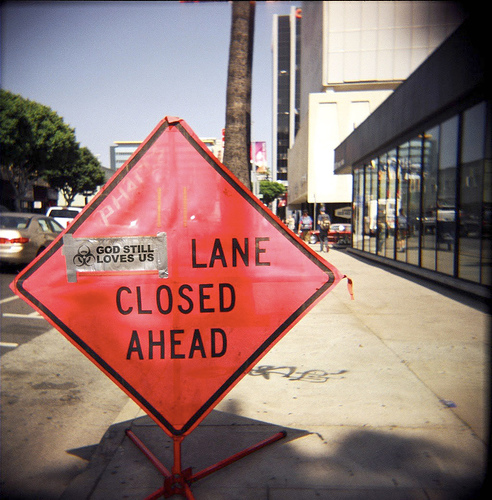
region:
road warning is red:
[24, 130, 374, 477]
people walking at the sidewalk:
[295, 196, 348, 253]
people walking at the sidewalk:
[289, 172, 352, 268]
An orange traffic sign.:
[8, 113, 357, 495]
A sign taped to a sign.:
[62, 232, 170, 284]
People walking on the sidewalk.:
[284, 206, 331, 252]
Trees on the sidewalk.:
[3, 86, 289, 212]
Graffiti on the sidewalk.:
[249, 364, 350, 383]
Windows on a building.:
[353, 104, 491, 288]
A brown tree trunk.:
[222, 2, 257, 198]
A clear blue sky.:
[1, 0, 301, 169]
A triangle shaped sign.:
[8, 114, 346, 439]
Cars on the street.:
[1, 204, 83, 266]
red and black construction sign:
[31, 185, 338, 408]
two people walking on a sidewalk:
[294, 198, 334, 239]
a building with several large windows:
[334, 110, 483, 267]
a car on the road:
[0, 196, 58, 273]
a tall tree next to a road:
[211, 1, 270, 208]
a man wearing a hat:
[318, 207, 327, 218]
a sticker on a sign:
[59, 220, 167, 283]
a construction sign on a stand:
[13, 117, 314, 498]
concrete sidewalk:
[327, 316, 457, 460]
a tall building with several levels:
[262, 4, 302, 185]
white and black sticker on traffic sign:
[54, 232, 173, 274]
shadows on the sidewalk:
[40, 414, 461, 495]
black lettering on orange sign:
[99, 242, 270, 372]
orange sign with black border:
[11, 103, 325, 440]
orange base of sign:
[112, 424, 288, 499]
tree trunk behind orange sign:
[217, 2, 262, 204]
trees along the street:
[6, 87, 106, 215]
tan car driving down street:
[7, 208, 66, 268]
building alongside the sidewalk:
[339, 43, 490, 297]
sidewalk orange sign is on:
[1, 175, 474, 497]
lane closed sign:
[12, 120, 338, 490]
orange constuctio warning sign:
[17, 116, 343, 497]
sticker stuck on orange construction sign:
[62, 234, 168, 273]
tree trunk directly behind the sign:
[227, 5, 250, 191]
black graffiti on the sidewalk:
[254, 364, 342, 387]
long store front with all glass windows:
[338, 20, 491, 289]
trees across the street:
[0, 91, 105, 204]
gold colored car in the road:
[0, 213, 62, 260]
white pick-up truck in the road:
[18, 206, 80, 227]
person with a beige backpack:
[316, 207, 329, 251]